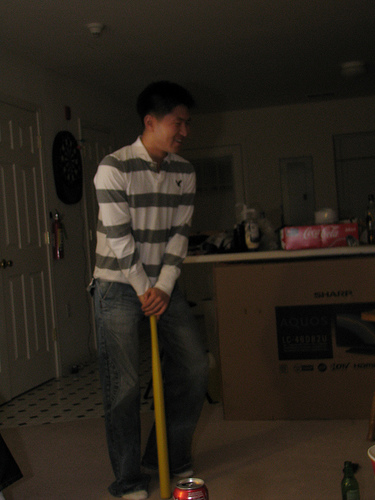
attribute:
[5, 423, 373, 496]
floor — beige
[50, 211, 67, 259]
hydrant — fire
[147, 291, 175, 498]
bat — yellow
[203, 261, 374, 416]
box — from new sharp tv, large, for a television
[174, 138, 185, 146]
smiling — man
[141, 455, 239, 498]
can — red, soda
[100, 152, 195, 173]
stripe — white and grey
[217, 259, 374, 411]
box — big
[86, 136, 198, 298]
shirt — long, white and grey, black and white , stripes 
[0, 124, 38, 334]
door — white in color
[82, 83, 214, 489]
man — sleeved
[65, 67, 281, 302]
boy — young, asian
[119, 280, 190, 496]
bat — baseball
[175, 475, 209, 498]
can — soda, in front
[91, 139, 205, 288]
shirt — long sleeved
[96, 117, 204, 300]
shirt — long sleeve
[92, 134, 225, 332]
shirt — striped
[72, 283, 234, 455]
jeans — blue in color